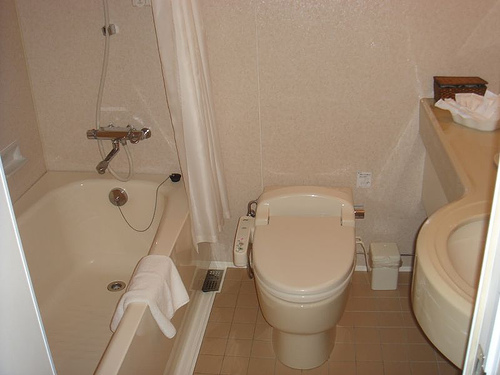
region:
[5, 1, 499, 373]
this bathroom looks very clean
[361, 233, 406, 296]
small wastebasket to the right of the toilet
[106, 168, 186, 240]
the stopper is attached by a metal chain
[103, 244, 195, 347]
cloth bath mat hanging on the edge of the tub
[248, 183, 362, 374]
toilet does not have a conventional tank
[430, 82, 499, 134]
tissue dispenser on the counter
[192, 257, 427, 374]
the floor is laid with light brown tile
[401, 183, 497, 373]
the sink extends beyond the counter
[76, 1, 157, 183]
the shower head looks to be detachable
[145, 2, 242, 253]
the shower curtain is white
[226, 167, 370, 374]
a white toilet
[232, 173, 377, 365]
a white toilet with the lid down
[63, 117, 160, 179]
a silver shower faucet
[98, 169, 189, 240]
a plug and chain for a tub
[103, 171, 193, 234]
a tub plug and chain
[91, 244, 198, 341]
a white towel resting on tub edge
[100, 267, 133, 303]
the drain in a tub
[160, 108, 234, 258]
the lower portion of a shower curtain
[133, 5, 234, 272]
the lower portion of a white shower curtain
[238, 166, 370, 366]
a toilet in the bathroom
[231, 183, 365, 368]
a white bidet toilet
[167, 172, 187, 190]
a black tub drain stopper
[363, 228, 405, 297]
a plastic white trash can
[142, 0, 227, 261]
a white shower curtain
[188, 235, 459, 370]
tan bathroom floor tiles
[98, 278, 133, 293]
a silver tub drain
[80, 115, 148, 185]
a silver tub faucet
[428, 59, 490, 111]
a brown wicker container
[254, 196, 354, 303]
a plastic toilet lid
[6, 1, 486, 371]
the inside of a restroom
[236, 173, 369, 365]
the toilet in a restroom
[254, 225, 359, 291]
the lid of a toilet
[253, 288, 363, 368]
the bowl of a toilet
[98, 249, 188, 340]
a white hand towel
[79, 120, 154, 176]
the faucet on a bathtub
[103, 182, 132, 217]
the drain control on a bathtub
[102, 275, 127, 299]
the drain to a bathtub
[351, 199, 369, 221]
the flush handle of a toilet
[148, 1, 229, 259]
a white shower curtain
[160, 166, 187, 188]
black drain plug for a bathtub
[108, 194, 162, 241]
metal chain attached to a drain plug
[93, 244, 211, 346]
a bath mat on the side of bathtub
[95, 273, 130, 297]
a silver bathtub drain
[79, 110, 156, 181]
silver water controls of a bathtub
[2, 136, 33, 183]
soap holder attached to a tile wall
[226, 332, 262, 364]
tan tile on a bathroom floor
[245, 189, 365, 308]
a white toilet seat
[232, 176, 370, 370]
a white bathroom toilet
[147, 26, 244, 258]
a white bathtub shower curtain